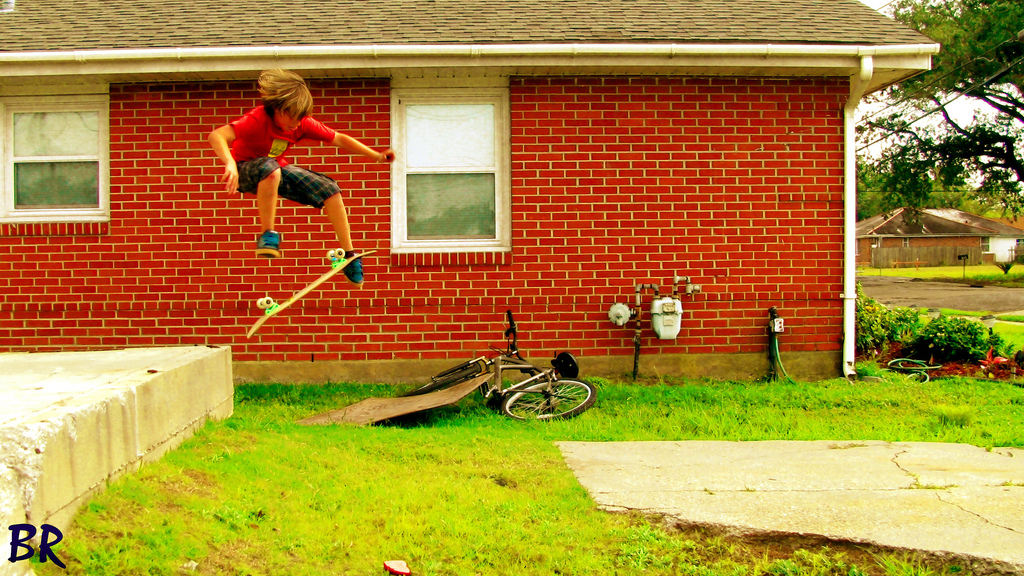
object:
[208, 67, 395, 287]
boy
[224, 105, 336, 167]
shirt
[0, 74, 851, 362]
wal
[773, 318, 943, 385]
hose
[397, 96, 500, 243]
window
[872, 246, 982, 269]
fence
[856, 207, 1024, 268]
house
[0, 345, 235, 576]
concrete slab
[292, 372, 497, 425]
wood piece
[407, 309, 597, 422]
bike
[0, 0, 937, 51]
roof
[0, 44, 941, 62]
drain pipe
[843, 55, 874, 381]
drain pipe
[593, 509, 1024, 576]
edge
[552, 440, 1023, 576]
concrete floor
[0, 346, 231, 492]
edge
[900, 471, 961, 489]
grass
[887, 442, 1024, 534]
crack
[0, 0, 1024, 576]
air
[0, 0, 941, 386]
building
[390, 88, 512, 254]
frame